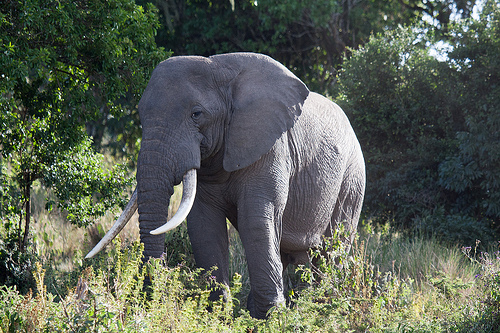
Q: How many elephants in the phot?
A: One.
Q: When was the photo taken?
A: Day time.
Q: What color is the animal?
A: Gray.